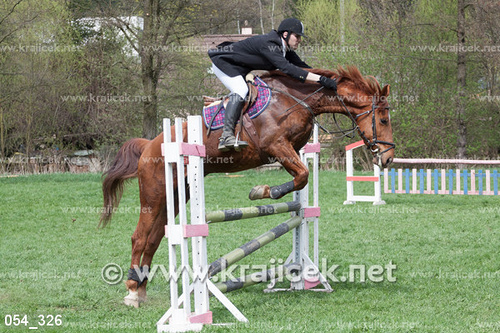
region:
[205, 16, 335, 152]
Man riding a brown horse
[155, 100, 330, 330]
White gate for horse to jump over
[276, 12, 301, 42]
Black cap on man's head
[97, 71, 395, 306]
Brown horse jumping over white gate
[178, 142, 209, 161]
Pink board on white jumping gate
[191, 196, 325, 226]
Lime and gray obstacle bar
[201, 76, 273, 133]
Pink and purple saddle pad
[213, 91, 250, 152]
Black riding boots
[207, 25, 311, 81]
Black jacket man is wearing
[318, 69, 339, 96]
Black glove on right hand of man riding the horse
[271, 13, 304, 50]
person wearing a black helmet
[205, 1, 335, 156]
person riding on a horse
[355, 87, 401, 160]
horse wearing a black bridle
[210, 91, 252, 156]
black boot in the stirrup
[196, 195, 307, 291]
green and purple poles on the jump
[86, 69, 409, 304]
horse going over a jump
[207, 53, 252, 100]
person wearing white pants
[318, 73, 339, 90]
person wearing black gloves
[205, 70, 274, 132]
red and blue saddle pad on a horse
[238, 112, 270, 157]
leather saddle strap around a horse's belly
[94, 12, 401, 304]
jockey and a horse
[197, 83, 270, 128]
pink and purple saddle blanket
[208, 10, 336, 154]
jockey straddling horse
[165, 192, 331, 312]
obstacle horse is jumping over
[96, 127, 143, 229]
brown tail on horse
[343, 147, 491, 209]
obstacles in the background`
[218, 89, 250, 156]
riding boots in stirrups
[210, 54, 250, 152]
white pants tucked into riding boots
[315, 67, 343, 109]
gloved hand holding onto reigns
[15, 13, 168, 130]
trees behind pasture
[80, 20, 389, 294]
person riding brown horse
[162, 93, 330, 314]
poles horse is jumping over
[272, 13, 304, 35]
black helmet of horse rider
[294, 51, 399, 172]
black reins of brown horse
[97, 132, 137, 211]
brown tail of horse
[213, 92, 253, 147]
black boots of rider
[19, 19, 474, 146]
trees along the jumping corse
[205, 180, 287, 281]
striped poles on the jumping course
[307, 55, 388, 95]
brown mane of the horse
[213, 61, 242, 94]
white pants of the rider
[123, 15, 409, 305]
A rider and a horse jumping over a hurtle.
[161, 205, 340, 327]
A horses hurtle with stripes.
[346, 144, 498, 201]
A horse obsticale course.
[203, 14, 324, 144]
A person riding a horse.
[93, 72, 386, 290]
A horse in mid jump.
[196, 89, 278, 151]
A riders' black boot.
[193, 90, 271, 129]
A plaid blanket to keep a sadle from rubbing.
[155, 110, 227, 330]
A red and white hurtle stand.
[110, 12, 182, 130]
A tree in the back ground of a horse show.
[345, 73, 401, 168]
A horses' brown head.